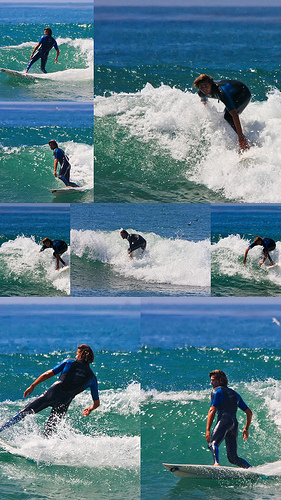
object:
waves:
[224, 144, 281, 199]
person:
[26, 23, 59, 76]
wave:
[70, 227, 211, 288]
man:
[120, 230, 148, 257]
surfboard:
[161, 461, 279, 478]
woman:
[193, 73, 251, 149]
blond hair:
[193, 73, 216, 86]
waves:
[65, 37, 91, 94]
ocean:
[0, 68, 95, 131]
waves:
[102, 71, 209, 164]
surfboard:
[193, 95, 255, 156]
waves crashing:
[70, 369, 140, 480]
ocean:
[1, 306, 134, 491]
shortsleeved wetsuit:
[208, 388, 250, 468]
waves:
[140, 385, 213, 412]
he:
[48, 139, 80, 188]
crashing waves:
[163, 234, 205, 289]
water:
[93, 0, 280, 202]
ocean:
[70, 203, 210, 296]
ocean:
[93, 0, 279, 202]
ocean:
[140, 294, 280, 500]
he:
[206, 369, 252, 467]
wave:
[0, 384, 159, 474]